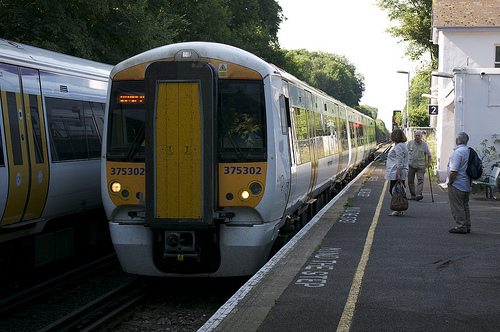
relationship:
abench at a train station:
[478, 166, 498, 186] [356, 157, 492, 295]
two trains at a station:
[4, 54, 354, 317] [77, 104, 498, 332]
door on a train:
[142, 72, 213, 272] [81, 102, 251, 292]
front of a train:
[78, 50, 259, 211] [203, 107, 360, 257]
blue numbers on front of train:
[222, 162, 266, 177] [278, 116, 305, 207]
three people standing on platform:
[366, 123, 479, 233] [212, 227, 463, 332]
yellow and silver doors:
[8, 167, 22, 211] [2, 95, 53, 214]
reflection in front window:
[216, 85, 262, 168] [195, 99, 257, 184]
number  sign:
[426, 105, 442, 120] [416, 100, 444, 132]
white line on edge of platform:
[191, 202, 333, 332] [182, 264, 488, 332]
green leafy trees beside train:
[230, 50, 364, 61] [277, 108, 342, 151]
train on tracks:
[95, 38, 385, 289] [44, 283, 229, 327]